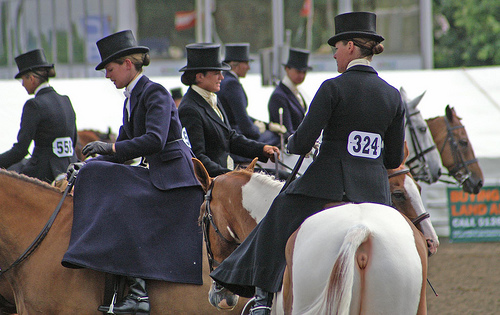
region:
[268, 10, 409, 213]
woman wearing a hat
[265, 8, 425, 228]
woman wearing black jacket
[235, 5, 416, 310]
woman wearing black boots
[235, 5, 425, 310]
woman ride a horse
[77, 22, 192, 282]
woman wearing black hat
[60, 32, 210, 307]
woman wearing black jacket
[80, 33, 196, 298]
woman wearing black gloves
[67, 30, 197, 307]
woman wearing black boots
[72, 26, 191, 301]
woman ride a horse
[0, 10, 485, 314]
Fancy people on horses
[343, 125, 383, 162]
Black numbers with a white background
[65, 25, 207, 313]
Woman wearing a black hat and black suit dress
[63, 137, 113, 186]
Pair of black leather gloves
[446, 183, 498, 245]
Green banner with orange and white writing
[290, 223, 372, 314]
White horse tail with a touch of brown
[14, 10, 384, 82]
Six black top hats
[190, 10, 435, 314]
Fancy woman on a horse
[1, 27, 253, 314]
Woman riding a horse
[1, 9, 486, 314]
Six people riding horses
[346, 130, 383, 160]
324 on back of woman's jacket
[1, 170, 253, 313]
beautiful brown horse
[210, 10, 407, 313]
woman wearing black suit and riding horse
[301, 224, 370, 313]
horses white and brown tail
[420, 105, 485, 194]
brown horses head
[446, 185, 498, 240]
green, orange, and white sign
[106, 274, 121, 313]
silver horse saddle stirrup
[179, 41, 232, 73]
black top hat on woman riding horse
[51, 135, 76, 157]
Numbers on back of woman's riding coat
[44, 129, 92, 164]
NUMBER ON BACK OF COAT IS 551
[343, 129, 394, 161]
NUMBER ON BACK OF COAT IS 324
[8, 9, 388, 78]
RIDERS ARE ALL WEARING TOP HATS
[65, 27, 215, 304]
WOMAN IS SITTING SIDE SADDLED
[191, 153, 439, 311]
HORSE IS TAN AND WHITE IN COLOR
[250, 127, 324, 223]
WOMAN IS HOLDING HORSE REINS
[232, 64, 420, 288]
WOMAN IS WEARING DRESSAGE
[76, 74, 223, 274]
DRESSAGE IS BLACK IN COLOR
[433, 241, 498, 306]
GROUND IS BROWN IN COLOR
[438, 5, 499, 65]
GREEN FOLIAGE IS IN THE BACKGROUND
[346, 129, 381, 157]
a number tag on the back of a dress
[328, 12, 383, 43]
a fancy black cap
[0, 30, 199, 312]
a woman in a purple dress riding a horse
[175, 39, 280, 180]
a pair of people in black clothes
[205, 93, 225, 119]
a yellow tie and white shirt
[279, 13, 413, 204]
a woman facing away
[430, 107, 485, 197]
a chestnut horse' head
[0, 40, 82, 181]
a woman in a black suit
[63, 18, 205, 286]
a woman in a purple suit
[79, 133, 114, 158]
a pair of black gloves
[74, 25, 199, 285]
woman sitting side saddle on horse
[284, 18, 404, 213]
woman sitting side saddle on horse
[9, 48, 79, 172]
woman sitting side saddle on horse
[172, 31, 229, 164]
woman sitting side saddle on horse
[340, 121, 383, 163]
black number on white bib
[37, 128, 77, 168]
black number on white bib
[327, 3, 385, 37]
black hat worn by woman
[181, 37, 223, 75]
black hat worn by woman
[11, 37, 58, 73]
black hat worn by woman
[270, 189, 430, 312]
back of the horse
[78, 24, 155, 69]
hat on person's head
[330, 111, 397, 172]
number on back of outfit